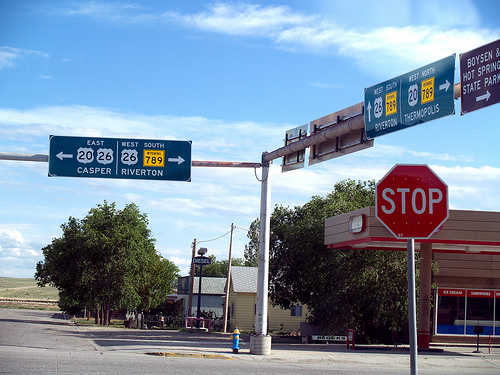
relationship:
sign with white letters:
[379, 163, 442, 248] [382, 184, 437, 218]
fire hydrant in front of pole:
[230, 289, 276, 356] [247, 138, 277, 355]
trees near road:
[46, 205, 155, 326] [17, 308, 207, 366]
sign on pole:
[46, 135, 193, 184] [247, 138, 277, 355]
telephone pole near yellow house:
[221, 219, 238, 335] [223, 265, 308, 332]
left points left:
[55, 150, 74, 161] [57, 149, 74, 162]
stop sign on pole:
[379, 163, 442, 248] [401, 241, 423, 369]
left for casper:
[55, 150, 74, 161] [77, 165, 113, 174]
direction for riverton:
[171, 155, 186, 164] [119, 168, 166, 178]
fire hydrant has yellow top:
[230, 289, 276, 356] [232, 324, 241, 332]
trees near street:
[46, 205, 155, 326] [42, 319, 104, 341]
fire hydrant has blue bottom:
[230, 289, 276, 356] [230, 338, 243, 352]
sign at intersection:
[379, 163, 442, 248] [39, 330, 392, 370]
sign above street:
[46, 135, 193, 184] [42, 319, 104, 341]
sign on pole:
[46, 135, 193, 184] [253, 135, 316, 352]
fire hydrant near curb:
[230, 289, 276, 356] [141, 347, 263, 362]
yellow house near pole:
[223, 265, 308, 332] [401, 241, 423, 369]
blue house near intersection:
[180, 274, 228, 327] [39, 330, 392, 370]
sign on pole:
[174, 272, 193, 297] [195, 258, 205, 334]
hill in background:
[3, 276, 72, 315] [7, 177, 148, 326]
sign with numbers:
[50, 137, 120, 181] [77, 146, 162, 168]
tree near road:
[46, 205, 155, 326] [17, 308, 207, 366]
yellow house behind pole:
[223, 265, 308, 332] [253, 135, 316, 352]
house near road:
[180, 274, 228, 327] [17, 308, 207, 366]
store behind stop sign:
[325, 205, 494, 354] [373, 156, 455, 364]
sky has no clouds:
[81, 29, 250, 99] [196, 5, 391, 62]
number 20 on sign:
[76, 147, 97, 162] [50, 137, 120, 181]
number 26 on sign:
[123, 149, 136, 163] [50, 137, 120, 181]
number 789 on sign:
[419, 78, 438, 102] [341, 57, 458, 123]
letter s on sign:
[383, 189, 398, 215] [379, 163, 442, 248]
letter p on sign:
[428, 186, 444, 213] [379, 163, 442, 248]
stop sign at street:
[373, 156, 455, 364] [42, 319, 104, 341]